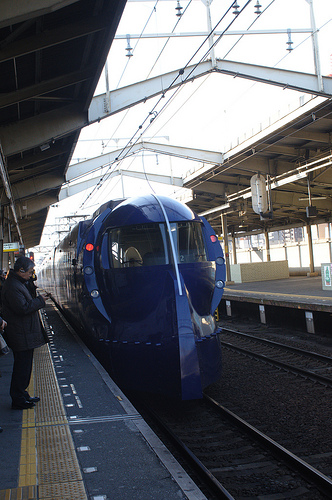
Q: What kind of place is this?
A: It is a station.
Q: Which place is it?
A: It is a station.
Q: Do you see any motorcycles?
A: No, there are no motorcycles.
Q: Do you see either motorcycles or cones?
A: No, there are no motorcycles or cones.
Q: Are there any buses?
A: No, there are no buses.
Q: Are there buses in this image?
A: No, there are no buses.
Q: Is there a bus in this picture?
A: No, there are no buses.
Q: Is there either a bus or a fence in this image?
A: No, there are no buses or fences.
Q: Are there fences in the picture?
A: No, there are no fences.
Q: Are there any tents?
A: No, there are no tents.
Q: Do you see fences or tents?
A: No, there are no tents or fences.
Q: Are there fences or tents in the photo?
A: No, there are no tents or fences.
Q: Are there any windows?
A: Yes, there is a window.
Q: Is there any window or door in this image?
A: Yes, there is a window.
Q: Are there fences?
A: No, there are no fences.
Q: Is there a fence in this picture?
A: No, there are no fences.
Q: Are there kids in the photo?
A: No, there are no kids.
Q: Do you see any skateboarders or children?
A: No, there are no children or skateboarders.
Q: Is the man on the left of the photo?
A: Yes, the man is on the left of the image.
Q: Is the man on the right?
A: No, the man is on the left of the image.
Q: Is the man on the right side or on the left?
A: The man is on the left of the image.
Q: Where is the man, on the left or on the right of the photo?
A: The man is on the left of the image.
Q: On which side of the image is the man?
A: The man is on the left of the image.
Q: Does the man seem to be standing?
A: Yes, the man is standing.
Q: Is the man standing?
A: Yes, the man is standing.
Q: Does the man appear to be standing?
A: Yes, the man is standing.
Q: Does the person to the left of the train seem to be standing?
A: Yes, the man is standing.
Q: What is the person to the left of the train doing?
A: The man is standing.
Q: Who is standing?
A: The man is standing.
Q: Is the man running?
A: No, the man is standing.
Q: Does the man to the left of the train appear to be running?
A: No, the man is standing.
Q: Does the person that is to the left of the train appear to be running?
A: No, the man is standing.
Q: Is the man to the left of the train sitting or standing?
A: The man is standing.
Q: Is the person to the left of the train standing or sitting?
A: The man is standing.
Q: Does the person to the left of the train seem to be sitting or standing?
A: The man is standing.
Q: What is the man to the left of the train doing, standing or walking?
A: The man is standing.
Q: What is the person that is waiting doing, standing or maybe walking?
A: The man is standing.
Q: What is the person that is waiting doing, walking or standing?
A: The man is standing.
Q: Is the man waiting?
A: Yes, the man is waiting.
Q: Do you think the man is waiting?
A: Yes, the man is waiting.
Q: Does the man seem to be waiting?
A: Yes, the man is waiting.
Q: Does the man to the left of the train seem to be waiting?
A: Yes, the man is waiting.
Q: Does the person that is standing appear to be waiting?
A: Yes, the man is waiting.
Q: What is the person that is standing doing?
A: The man is waiting.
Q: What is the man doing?
A: The man is waiting.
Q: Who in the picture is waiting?
A: The man is waiting.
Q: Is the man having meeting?
A: No, the man is waiting.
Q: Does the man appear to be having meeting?
A: No, the man is waiting.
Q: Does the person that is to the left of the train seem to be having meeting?
A: No, the man is waiting.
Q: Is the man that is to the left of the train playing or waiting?
A: The man is waiting.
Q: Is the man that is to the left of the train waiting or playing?
A: The man is waiting.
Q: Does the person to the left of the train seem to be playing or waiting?
A: The man is waiting.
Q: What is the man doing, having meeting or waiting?
A: The man is waiting.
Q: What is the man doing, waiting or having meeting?
A: The man is waiting.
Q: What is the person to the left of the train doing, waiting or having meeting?
A: The man is waiting.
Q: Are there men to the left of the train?
A: Yes, there is a man to the left of the train.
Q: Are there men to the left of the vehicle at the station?
A: Yes, there is a man to the left of the train.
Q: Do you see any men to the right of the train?
A: No, the man is to the left of the train.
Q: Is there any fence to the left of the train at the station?
A: No, there is a man to the left of the train.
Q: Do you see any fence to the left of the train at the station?
A: No, there is a man to the left of the train.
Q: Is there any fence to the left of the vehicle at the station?
A: No, there is a man to the left of the train.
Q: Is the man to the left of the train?
A: Yes, the man is to the left of the train.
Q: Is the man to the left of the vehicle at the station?
A: Yes, the man is to the left of the train.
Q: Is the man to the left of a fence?
A: No, the man is to the left of the train.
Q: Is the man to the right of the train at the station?
A: No, the man is to the left of the train.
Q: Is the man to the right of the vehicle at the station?
A: No, the man is to the left of the train.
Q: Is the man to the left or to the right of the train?
A: The man is to the left of the train.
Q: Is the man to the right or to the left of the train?
A: The man is to the left of the train.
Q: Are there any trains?
A: Yes, there is a train.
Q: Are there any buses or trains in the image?
A: Yes, there is a train.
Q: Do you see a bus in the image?
A: No, there are no buses.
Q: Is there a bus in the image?
A: No, there are no buses.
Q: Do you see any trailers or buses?
A: No, there are no buses or trailers.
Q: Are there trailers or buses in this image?
A: No, there are no buses or trailers.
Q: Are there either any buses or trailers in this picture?
A: No, there are no buses or trailers.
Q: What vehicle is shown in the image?
A: The vehicle is a train.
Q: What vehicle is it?
A: The vehicle is a train.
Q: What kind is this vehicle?
A: This is a train.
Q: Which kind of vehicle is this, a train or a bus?
A: This is a train.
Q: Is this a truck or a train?
A: This is a train.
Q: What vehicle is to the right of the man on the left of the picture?
A: The vehicle is a train.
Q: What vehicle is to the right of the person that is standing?
A: The vehicle is a train.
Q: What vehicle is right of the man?
A: The vehicle is a train.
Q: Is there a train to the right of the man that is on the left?
A: Yes, there is a train to the right of the man.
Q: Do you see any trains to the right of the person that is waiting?
A: Yes, there is a train to the right of the man.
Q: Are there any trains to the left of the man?
A: No, the train is to the right of the man.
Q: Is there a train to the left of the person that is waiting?
A: No, the train is to the right of the man.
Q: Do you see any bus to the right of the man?
A: No, there is a train to the right of the man.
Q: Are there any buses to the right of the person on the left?
A: No, there is a train to the right of the man.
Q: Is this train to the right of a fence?
A: No, the train is to the right of a man.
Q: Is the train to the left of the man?
A: No, the train is to the right of the man.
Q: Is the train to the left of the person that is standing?
A: No, the train is to the right of the man.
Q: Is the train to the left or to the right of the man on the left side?
A: The train is to the right of the man.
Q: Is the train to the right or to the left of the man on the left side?
A: The train is to the right of the man.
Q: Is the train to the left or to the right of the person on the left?
A: The train is to the right of the man.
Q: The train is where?
A: The train is at the station.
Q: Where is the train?
A: The train is at the station.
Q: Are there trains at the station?
A: Yes, there is a train at the station.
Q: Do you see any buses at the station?
A: No, there is a train at the station.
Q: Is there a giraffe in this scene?
A: No, there are no giraffes.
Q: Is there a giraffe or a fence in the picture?
A: No, there are no giraffes or fences.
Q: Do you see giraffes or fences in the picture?
A: No, there are no giraffes or fences.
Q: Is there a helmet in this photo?
A: No, there are no helmets.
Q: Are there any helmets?
A: No, there are no helmets.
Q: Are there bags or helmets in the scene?
A: No, there are no helmets or bags.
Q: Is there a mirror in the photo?
A: No, there are no mirrors.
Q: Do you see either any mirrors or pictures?
A: No, there are no mirrors or pictures.